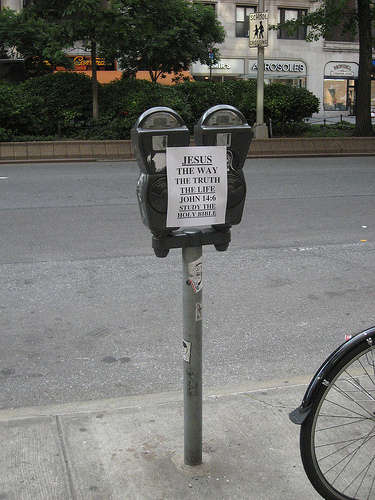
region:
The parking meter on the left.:
[129, 97, 200, 241]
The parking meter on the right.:
[199, 103, 249, 226]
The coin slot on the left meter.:
[152, 133, 168, 150]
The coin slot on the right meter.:
[214, 132, 232, 146]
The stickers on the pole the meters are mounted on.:
[181, 255, 206, 365]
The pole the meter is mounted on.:
[182, 245, 203, 466]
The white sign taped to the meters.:
[164, 146, 228, 226]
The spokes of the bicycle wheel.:
[313, 346, 374, 493]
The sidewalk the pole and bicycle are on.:
[1, 386, 374, 499]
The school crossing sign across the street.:
[246, 10, 271, 49]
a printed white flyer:
[153, 135, 243, 240]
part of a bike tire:
[292, 315, 369, 495]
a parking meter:
[90, 92, 260, 478]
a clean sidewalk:
[6, 349, 366, 491]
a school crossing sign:
[232, 3, 296, 138]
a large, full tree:
[13, 0, 226, 154]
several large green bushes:
[0, 58, 348, 153]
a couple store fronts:
[235, 4, 371, 169]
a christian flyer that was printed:
[158, 138, 230, 232]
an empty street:
[5, 102, 367, 420]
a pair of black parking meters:
[131, 104, 251, 465]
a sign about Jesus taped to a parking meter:
[167, 146, 225, 225]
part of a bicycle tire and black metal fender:
[288, 325, 373, 499]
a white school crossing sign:
[247, 12, 265, 46]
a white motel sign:
[322, 61, 360, 79]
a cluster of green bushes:
[0, 71, 316, 141]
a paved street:
[0, 162, 373, 405]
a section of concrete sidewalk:
[1, 366, 373, 499]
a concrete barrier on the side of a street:
[3, 139, 373, 159]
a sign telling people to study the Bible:
[166, 147, 227, 227]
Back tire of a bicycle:
[276, 319, 366, 467]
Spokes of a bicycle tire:
[335, 374, 370, 480]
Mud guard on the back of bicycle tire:
[284, 327, 365, 431]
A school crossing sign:
[244, 4, 270, 49]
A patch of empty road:
[284, 191, 371, 307]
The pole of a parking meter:
[174, 266, 211, 475]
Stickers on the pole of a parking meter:
[182, 254, 205, 365]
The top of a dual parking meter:
[127, 102, 254, 143]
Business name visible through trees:
[55, 48, 119, 74]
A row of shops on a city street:
[190, 52, 359, 103]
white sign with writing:
[154, 142, 239, 223]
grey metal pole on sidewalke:
[174, 252, 223, 473]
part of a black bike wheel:
[290, 312, 372, 496]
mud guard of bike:
[288, 329, 372, 437]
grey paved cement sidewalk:
[23, 405, 314, 496]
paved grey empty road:
[13, 149, 341, 353]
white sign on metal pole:
[230, 11, 315, 135]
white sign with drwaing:
[251, 12, 270, 44]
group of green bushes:
[0, 80, 324, 125]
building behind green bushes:
[159, 49, 351, 81]